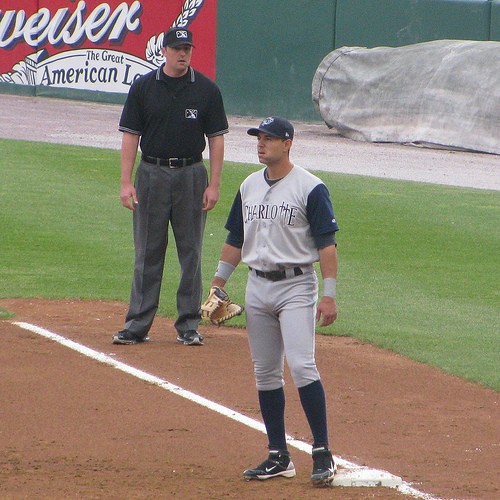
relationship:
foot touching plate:
[309, 448, 336, 486] [332, 466, 403, 489]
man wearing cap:
[114, 27, 227, 348] [160, 25, 197, 48]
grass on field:
[1, 131, 498, 376] [0, 93, 485, 499]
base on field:
[332, 466, 404, 493] [0, 93, 485, 499]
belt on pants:
[247, 261, 314, 283] [246, 266, 320, 386]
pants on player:
[246, 266, 320, 386] [197, 115, 337, 487]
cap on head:
[247, 115, 294, 140] [249, 112, 297, 169]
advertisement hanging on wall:
[0, 0, 217, 94] [2, 0, 498, 152]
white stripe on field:
[15, 350, 245, 431] [7, 138, 117, 295]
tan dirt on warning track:
[0, 93, 496, 196] [1, 92, 485, 189]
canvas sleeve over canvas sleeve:
[314, 32, 459, 156] [311, 38, 499, 154]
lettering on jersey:
[245, 197, 365, 232] [207, 159, 355, 296]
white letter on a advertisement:
[100, 0, 142, 47] [0, 0, 217, 94]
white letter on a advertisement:
[83, 4, 111, 44] [0, 0, 217, 94]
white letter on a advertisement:
[59, 0, 89, 53] [0, 0, 217, 94]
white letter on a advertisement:
[18, 7, 48, 47] [0, 0, 217, 94]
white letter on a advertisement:
[0, 8, 29, 47] [0, 0, 217, 94]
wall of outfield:
[228, 4, 316, 114] [2, 95, 488, 298]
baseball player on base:
[207, 115, 337, 485] [332, 466, 404, 493]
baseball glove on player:
[200, 285, 245, 325] [197, 115, 337, 487]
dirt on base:
[334, 468, 365, 476] [332, 466, 404, 493]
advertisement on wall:
[3, 2, 232, 120] [1, 1, 485, 125]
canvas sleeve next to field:
[311, 38, 499, 154] [0, 93, 485, 499]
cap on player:
[247, 115, 294, 140] [197, 115, 337, 487]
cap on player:
[247, 115, 294, 140] [111, 25, 232, 352]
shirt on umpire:
[119, 63, 230, 156] [114, 26, 229, 346]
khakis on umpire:
[122, 151, 202, 340] [114, 26, 229, 346]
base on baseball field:
[332, 466, 404, 493] [1, 94, 485, 497]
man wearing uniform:
[201, 116, 336, 487] [236, 117, 381, 483]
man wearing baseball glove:
[201, 116, 336, 487] [200, 285, 245, 325]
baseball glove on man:
[193, 283, 243, 331] [194, 112, 343, 489]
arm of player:
[295, 186, 365, 318] [197, 115, 337, 487]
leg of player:
[229, 365, 288, 494] [204, 103, 350, 492]